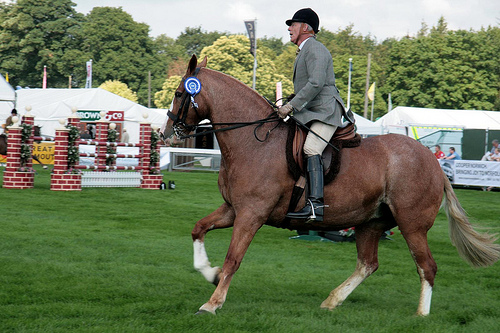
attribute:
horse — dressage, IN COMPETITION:
[152, 50, 498, 330]